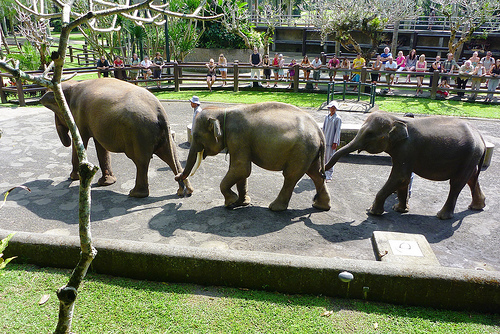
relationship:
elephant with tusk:
[29, 64, 401, 219] [168, 132, 213, 183]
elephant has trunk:
[29, 64, 401, 219] [151, 130, 207, 200]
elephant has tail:
[29, 64, 401, 219] [152, 115, 188, 184]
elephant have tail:
[29, 64, 401, 219] [152, 115, 188, 184]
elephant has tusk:
[29, 64, 401, 219] [168, 132, 213, 183]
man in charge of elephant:
[281, 74, 367, 167] [29, 64, 401, 219]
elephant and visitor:
[29, 64, 401, 219] [234, 34, 446, 82]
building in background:
[242, 1, 473, 53] [96, 14, 471, 116]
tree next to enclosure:
[15, 168, 173, 296] [3, 67, 483, 304]